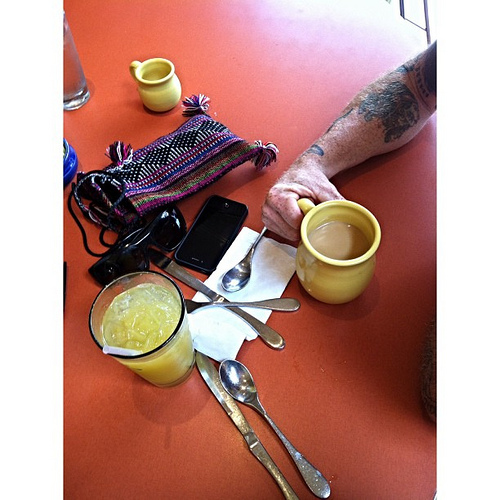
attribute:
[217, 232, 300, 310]
napkin — white 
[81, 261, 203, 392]
glass — large 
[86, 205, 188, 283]
sunglasses — black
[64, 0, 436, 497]
tabletop — red 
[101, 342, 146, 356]
straw — white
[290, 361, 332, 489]
spoon — silver 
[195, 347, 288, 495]
knife — silver